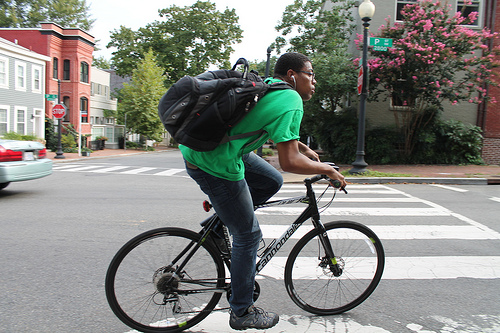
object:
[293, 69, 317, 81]
glasses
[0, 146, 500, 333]
road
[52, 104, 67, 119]
stop sign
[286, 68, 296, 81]
earbud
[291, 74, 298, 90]
earplugs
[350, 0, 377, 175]
street lamp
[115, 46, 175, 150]
tree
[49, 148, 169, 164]
curb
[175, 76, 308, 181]
green shirt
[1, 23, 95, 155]
building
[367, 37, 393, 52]
sign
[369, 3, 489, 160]
tree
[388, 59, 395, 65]
blooms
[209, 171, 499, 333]
crosswalk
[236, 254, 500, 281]
lines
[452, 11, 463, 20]
flower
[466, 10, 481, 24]
flower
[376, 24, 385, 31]
flower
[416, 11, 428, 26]
flower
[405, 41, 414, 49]
flower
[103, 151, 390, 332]
bicycle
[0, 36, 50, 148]
grey building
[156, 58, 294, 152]
backpack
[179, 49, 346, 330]
boy